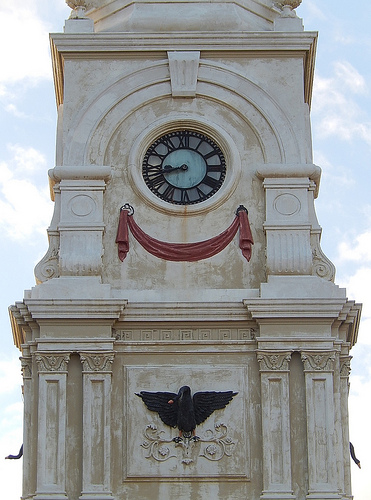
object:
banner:
[114, 203, 256, 264]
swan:
[133, 382, 241, 444]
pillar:
[241, 288, 350, 499]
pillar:
[19, 295, 132, 500]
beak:
[165, 390, 181, 406]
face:
[143, 132, 227, 204]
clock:
[125, 111, 243, 215]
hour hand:
[151, 162, 190, 176]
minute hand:
[146, 160, 187, 178]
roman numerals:
[143, 132, 225, 203]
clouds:
[0, 141, 56, 241]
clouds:
[0, 1, 56, 95]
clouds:
[330, 228, 371, 301]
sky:
[0, 1, 371, 500]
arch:
[60, 56, 310, 170]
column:
[50, 164, 115, 274]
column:
[252, 160, 324, 275]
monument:
[8, 0, 363, 499]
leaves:
[136, 421, 236, 465]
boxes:
[156, 324, 173, 343]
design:
[34, 349, 115, 372]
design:
[254, 346, 337, 372]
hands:
[149, 160, 189, 180]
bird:
[347, 438, 361, 471]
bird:
[5, 438, 24, 463]